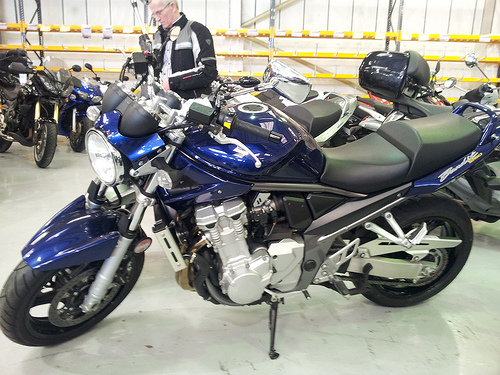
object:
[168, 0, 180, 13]
ear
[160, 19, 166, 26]
mouth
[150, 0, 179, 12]
hair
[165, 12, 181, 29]
neck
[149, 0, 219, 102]
man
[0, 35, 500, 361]
bike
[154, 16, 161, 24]
man's nose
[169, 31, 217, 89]
arm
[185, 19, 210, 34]
shoulder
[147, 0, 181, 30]
head